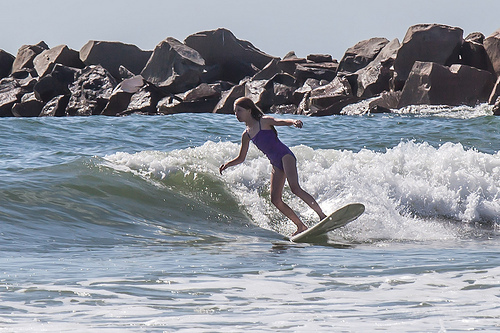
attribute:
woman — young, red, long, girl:
[219, 97, 327, 232]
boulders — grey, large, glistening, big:
[5, 24, 499, 100]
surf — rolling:
[100, 128, 497, 246]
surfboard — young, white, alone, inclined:
[218, 92, 374, 253]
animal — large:
[126, 74, 179, 117]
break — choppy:
[90, 134, 497, 323]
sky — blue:
[2, 1, 496, 35]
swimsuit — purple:
[250, 127, 292, 170]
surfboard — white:
[289, 192, 366, 247]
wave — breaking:
[122, 140, 485, 236]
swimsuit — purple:
[247, 125, 292, 179]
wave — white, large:
[10, 133, 497, 254]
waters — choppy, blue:
[49, 129, 476, 316]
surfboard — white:
[276, 203, 369, 254]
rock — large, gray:
[296, 33, 483, 101]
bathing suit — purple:
[246, 102, 292, 180]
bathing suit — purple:
[245, 115, 297, 172]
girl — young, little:
[217, 100, 329, 242]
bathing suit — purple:
[256, 130, 292, 173]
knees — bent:
[257, 177, 318, 209]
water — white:
[112, 145, 292, 188]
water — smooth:
[30, 159, 84, 270]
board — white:
[289, 196, 365, 243]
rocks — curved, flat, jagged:
[276, 35, 477, 115]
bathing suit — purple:
[247, 126, 290, 155]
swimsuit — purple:
[253, 131, 293, 171]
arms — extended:
[210, 134, 252, 179]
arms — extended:
[269, 114, 311, 134]